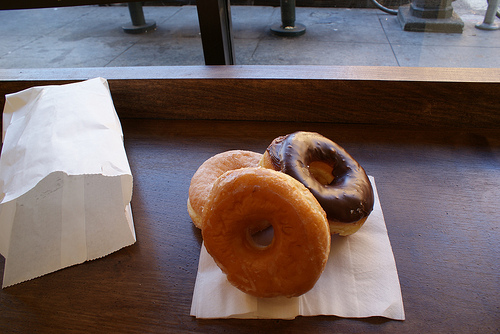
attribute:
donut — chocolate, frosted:
[265, 123, 382, 246]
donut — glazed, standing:
[192, 166, 337, 306]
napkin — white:
[188, 149, 414, 320]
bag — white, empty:
[0, 72, 145, 287]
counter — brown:
[2, 65, 499, 334]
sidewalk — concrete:
[1, 3, 500, 71]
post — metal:
[269, 1, 314, 40]